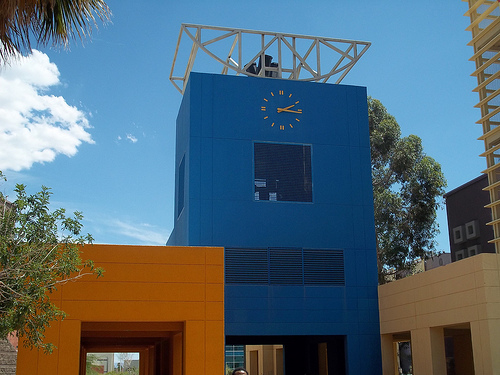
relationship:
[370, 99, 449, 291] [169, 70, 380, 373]
tree next to building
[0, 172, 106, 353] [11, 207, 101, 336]
tree has branches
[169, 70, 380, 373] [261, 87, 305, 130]
building has clock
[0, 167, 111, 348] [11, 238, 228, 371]
tree in front of building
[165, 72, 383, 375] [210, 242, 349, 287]
building has window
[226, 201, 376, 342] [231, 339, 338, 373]
wall has gap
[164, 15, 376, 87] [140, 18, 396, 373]
antenna on building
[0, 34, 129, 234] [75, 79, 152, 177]
cloud in sky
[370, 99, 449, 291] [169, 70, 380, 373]
tree in background of building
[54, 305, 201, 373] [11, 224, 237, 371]
breezeway through building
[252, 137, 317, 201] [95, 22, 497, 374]
window on building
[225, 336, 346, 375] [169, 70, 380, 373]
gap in front of building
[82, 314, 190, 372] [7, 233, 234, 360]
opening in front of building